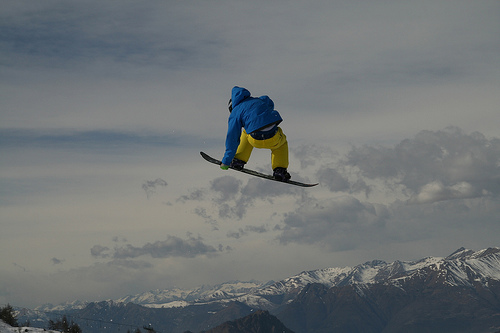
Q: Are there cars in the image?
A: No, there are no cars.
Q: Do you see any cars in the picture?
A: No, there are no cars.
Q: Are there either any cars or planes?
A: No, there are no cars or planes.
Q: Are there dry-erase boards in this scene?
A: No, there are no dry-erase boards.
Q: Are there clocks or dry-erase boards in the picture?
A: No, there are no dry-erase boards or clocks.